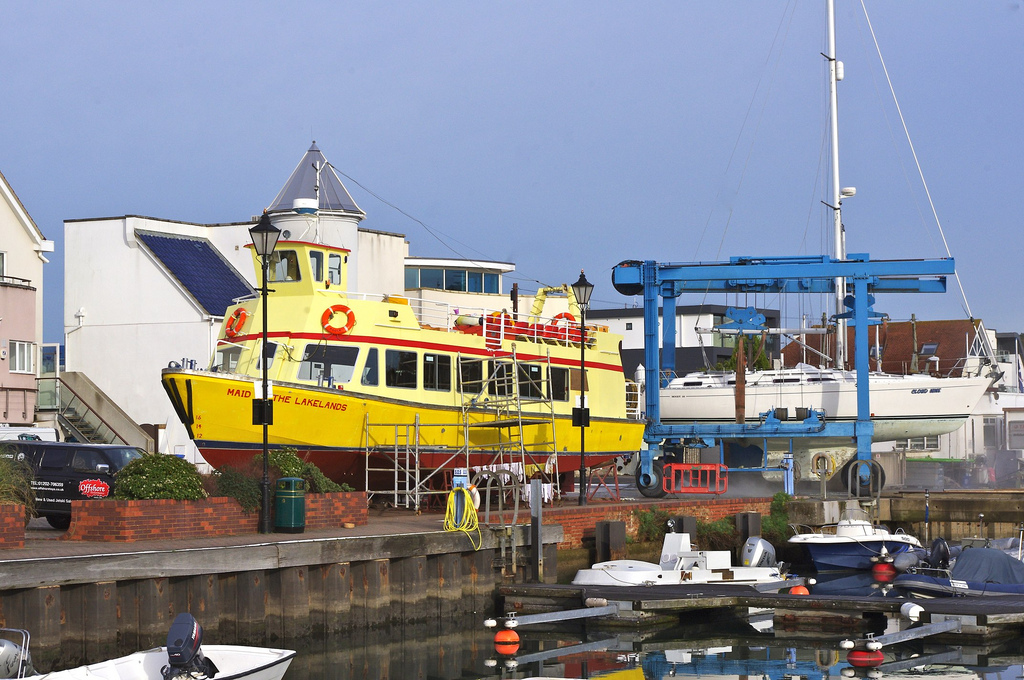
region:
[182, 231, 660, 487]
The yellow vessel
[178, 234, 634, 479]
A yellow boat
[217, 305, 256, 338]
A life preserver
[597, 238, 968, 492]
The blue construction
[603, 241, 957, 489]
A blue construction crane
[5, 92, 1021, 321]
The clear blue sky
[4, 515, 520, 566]
The concrete sidewalk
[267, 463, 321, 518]
The green garbage can on the sidewalk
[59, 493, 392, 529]
The red brick wall behind the garbage can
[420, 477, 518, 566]
cord is yellow in color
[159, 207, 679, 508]
boat is yellow in color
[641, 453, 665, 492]
wheels are black in color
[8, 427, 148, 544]
van is black in color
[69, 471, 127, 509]
van has logo on the side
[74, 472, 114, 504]
logo on can is red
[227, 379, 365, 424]
yellow boat has read text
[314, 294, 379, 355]
red life preserver on boat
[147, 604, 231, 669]
black motor on boat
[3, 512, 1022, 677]
the boats in the water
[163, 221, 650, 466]
a yellow ship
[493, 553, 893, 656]
the orange floaters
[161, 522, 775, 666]
the motors on the boats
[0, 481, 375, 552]
the brick wall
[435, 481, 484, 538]
the yellow rope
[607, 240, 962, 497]
the blue crane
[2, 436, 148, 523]
a black and white van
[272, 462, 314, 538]
a trash can on dock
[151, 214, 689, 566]
A large yellow and red boat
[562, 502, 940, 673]
Boats in the water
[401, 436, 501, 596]
A yellow rope next to the big boats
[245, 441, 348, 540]
A green trashcan next to streetlight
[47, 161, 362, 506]
a lg white house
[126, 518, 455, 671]
A brick wall next to the water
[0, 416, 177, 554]
A black van parked in front of the boat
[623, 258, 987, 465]
A large white boat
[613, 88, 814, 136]
a clear sky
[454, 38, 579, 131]
a clear blue sky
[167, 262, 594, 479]
a boat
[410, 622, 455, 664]
the water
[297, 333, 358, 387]
a window on the boat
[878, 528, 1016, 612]
a blue boat in the water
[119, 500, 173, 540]
a small brick wall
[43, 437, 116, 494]
a truck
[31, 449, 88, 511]
the truck is black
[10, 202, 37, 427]
a building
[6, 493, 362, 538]
brick wall along the walkway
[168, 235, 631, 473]
yellow boat beside the white building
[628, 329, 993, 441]
white boat on the blue lift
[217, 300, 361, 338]
life rings on the yellow boat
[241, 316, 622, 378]
red stripe on the yellow boat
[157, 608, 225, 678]
black engine on the white boat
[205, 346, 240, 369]
a window on a boat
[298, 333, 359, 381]
a window on a boat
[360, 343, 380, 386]
a window on a boat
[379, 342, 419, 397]
a window on a boat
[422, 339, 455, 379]
a window on a boat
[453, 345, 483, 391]
a window on a boat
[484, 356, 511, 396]
a window on a boat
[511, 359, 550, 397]
a window on a boat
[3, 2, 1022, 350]
the sky appears blue and unclouded